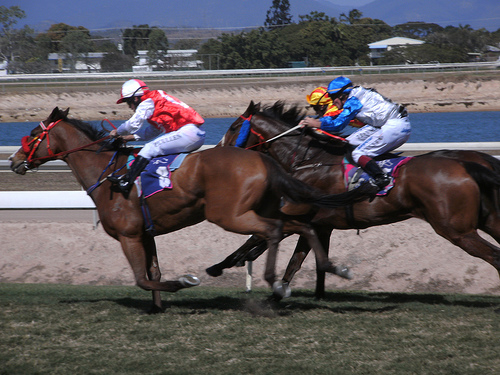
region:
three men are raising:
[26, 51, 498, 321]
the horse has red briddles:
[12, 103, 127, 183]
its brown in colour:
[69, 170, 239, 249]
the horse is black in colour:
[417, 165, 457, 240]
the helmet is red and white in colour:
[94, 72, 144, 96]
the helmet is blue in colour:
[322, 63, 352, 98]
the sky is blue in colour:
[141, 5, 260, 25]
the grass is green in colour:
[86, 264, 283, 369]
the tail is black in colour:
[241, 152, 350, 212]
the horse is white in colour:
[373, 33, 433, 70]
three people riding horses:
[10, 79, 491, 308]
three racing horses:
[8, 89, 496, 307]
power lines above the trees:
[63, 17, 373, 59]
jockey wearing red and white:
[106, 78, 198, 190]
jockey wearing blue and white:
[325, 75, 401, 190]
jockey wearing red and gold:
[307, 86, 335, 121]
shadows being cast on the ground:
[65, 288, 476, 316]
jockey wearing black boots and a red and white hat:
[107, 82, 200, 202]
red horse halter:
[11, 115, 87, 168]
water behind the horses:
[422, 110, 492, 140]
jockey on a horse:
[23, 66, 321, 331]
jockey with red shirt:
[18, 71, 293, 288]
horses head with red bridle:
[13, 98, 99, 203]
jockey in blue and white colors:
[315, 73, 412, 196]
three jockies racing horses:
[20, 58, 495, 348]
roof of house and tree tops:
[355, 21, 439, 65]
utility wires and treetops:
[3, 16, 321, 64]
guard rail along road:
[2, 58, 495, 83]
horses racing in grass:
[12, 59, 495, 364]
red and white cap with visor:
[111, 73, 148, 103]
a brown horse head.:
[6, 97, 86, 192]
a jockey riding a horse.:
[104, 54, 219, 202]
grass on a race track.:
[6, 277, 495, 374]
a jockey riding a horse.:
[311, 60, 421, 187]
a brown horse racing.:
[214, 90, 498, 300]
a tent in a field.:
[355, 33, 434, 74]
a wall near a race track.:
[9, 92, 498, 163]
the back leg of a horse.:
[189, 128, 272, 296]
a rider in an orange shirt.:
[126, 77, 214, 151]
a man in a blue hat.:
[330, 71, 358, 105]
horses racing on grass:
[9, 55, 499, 369]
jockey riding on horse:
[14, 66, 316, 314]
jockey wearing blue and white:
[314, 63, 444, 201]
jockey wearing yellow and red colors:
[292, 66, 357, 153]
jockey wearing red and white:
[119, 67, 237, 162]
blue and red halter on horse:
[222, 99, 296, 170]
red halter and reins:
[13, 105, 124, 167]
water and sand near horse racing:
[226, 62, 498, 299]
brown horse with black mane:
[13, 99, 192, 203]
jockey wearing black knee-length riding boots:
[61, 70, 214, 205]